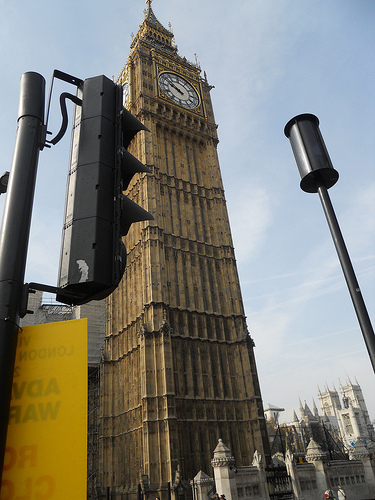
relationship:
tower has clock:
[96, 2, 269, 499] [155, 67, 204, 109]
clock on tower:
[155, 67, 204, 109] [96, 2, 269, 499]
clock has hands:
[155, 67, 204, 109] [165, 75, 185, 97]